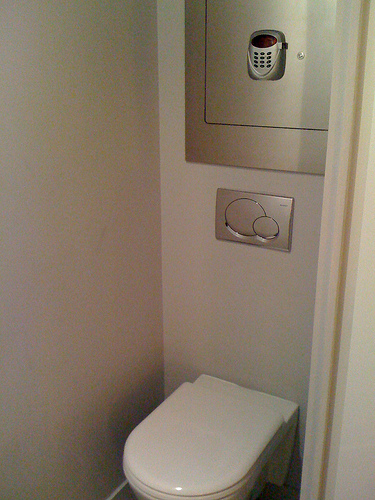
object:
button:
[253, 50, 258, 55]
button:
[253, 63, 258, 67]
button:
[266, 50, 271, 55]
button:
[266, 63, 272, 67]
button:
[259, 59, 264, 63]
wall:
[160, 1, 335, 489]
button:
[252, 53, 258, 59]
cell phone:
[246, 27, 288, 82]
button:
[265, 50, 271, 55]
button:
[264, 56, 273, 60]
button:
[263, 63, 272, 67]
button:
[251, 63, 257, 68]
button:
[251, 48, 257, 56]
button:
[264, 63, 271, 67]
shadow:
[114, 367, 184, 412]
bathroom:
[0, 0, 373, 498]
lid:
[123, 380, 299, 498]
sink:
[137, 382, 275, 486]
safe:
[184, 1, 333, 178]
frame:
[308, 175, 355, 478]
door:
[198, 1, 335, 136]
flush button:
[217, 184, 293, 249]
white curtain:
[300, 0, 374, 499]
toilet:
[122, 371, 300, 499]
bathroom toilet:
[123, 373, 299, 499]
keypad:
[246, 25, 288, 81]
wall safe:
[184, 2, 336, 173]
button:
[257, 65, 262, 68]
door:
[293, 6, 373, 495]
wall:
[0, 8, 162, 500]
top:
[122, 362, 301, 498]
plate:
[225, 199, 278, 239]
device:
[247, 29, 287, 79]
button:
[253, 55, 259, 60]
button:
[258, 55, 263, 59]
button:
[253, 60, 258, 64]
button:
[258, 60, 264, 63]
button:
[259, 65, 264, 68]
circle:
[293, 48, 307, 61]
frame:
[299, 0, 374, 498]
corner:
[152, 0, 170, 400]